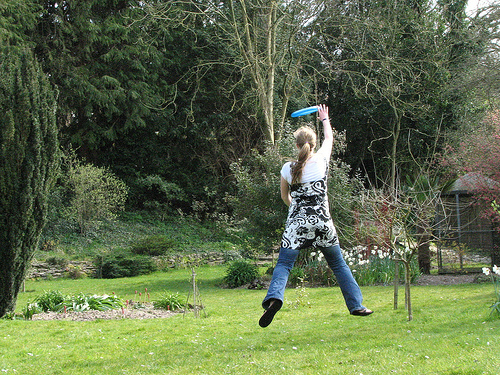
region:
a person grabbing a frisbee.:
[243, 99, 380, 338]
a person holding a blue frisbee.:
[283, 90, 347, 121]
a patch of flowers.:
[6, 269, 223, 349]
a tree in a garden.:
[203, 1, 324, 155]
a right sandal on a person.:
[350, 299, 377, 325]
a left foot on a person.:
[247, 289, 294, 339]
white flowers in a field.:
[307, 174, 434, 295]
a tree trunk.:
[416, 176, 476, 286]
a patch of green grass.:
[1, 279, 498, 369]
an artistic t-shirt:
[271, 170, 340, 251]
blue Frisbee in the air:
[292, 106, 319, 121]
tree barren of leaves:
[358, 183, 460, 328]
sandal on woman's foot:
[249, 298, 285, 330]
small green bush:
[105, 249, 157, 281]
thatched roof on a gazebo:
[437, 176, 498, 204]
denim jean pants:
[264, 248, 359, 301]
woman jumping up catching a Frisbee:
[251, 93, 370, 328]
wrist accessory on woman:
[315, 113, 331, 125]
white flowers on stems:
[354, 244, 394, 265]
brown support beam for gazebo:
[450, 193, 471, 272]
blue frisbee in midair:
[287, 101, 324, 119]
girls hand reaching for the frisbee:
[313, 101, 335, 166]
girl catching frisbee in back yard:
[244, 100, 381, 337]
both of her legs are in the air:
[255, 101, 385, 332]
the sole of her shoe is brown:
[257, 296, 287, 333]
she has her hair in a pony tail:
[285, 124, 318, 186]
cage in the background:
[438, 168, 497, 278]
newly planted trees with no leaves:
[354, 180, 462, 330]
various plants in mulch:
[20, 292, 212, 324]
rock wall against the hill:
[23, 248, 242, 280]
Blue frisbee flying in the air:
[290, 105, 320, 117]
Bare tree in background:
[225, 5, 290, 160]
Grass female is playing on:
[0, 276, 493, 371]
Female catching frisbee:
[260, 100, 370, 325]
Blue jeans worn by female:
[255, 245, 367, 308]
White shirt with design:
[270, 145, 340, 251]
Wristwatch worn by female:
[315, 111, 332, 121]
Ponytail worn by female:
[287, 140, 307, 185]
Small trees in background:
[63, 161, 133, 241]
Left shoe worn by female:
[258, 296, 282, 328]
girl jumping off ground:
[226, 86, 388, 350]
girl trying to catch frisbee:
[267, 90, 379, 330]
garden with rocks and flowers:
[27, 282, 211, 324]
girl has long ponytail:
[259, 96, 353, 318]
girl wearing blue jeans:
[266, 91, 381, 354]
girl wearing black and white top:
[264, 108, 341, 268]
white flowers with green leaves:
[344, 234, 444, 296]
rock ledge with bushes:
[28, 229, 218, 276]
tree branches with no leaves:
[144, 6, 314, 118]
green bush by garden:
[0, 119, 147, 369]